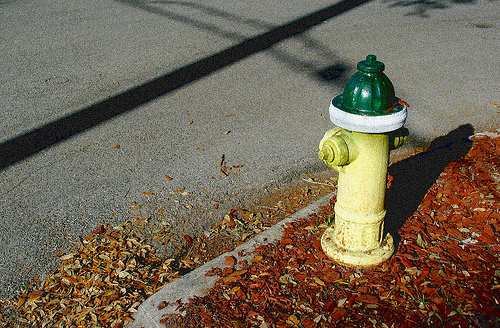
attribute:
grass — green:
[413, 290, 431, 310]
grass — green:
[441, 296, 453, 307]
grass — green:
[325, 211, 334, 225]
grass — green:
[312, 214, 320, 231]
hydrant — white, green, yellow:
[316, 52, 411, 269]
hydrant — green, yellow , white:
[293, 25, 427, 326]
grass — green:
[412, 285, 427, 310]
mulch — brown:
[186, 265, 315, 322]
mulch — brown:
[264, 224, 317, 260]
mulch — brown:
[400, 143, 496, 321]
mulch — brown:
[410, 200, 490, 245]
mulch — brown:
[417, 258, 491, 303]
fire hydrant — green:
[310, 52, 416, 273]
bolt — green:
[364, 53, 376, 66]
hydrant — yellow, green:
[309, 47, 419, 272]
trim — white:
[327, 99, 407, 134]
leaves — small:
[384, 93, 414, 114]